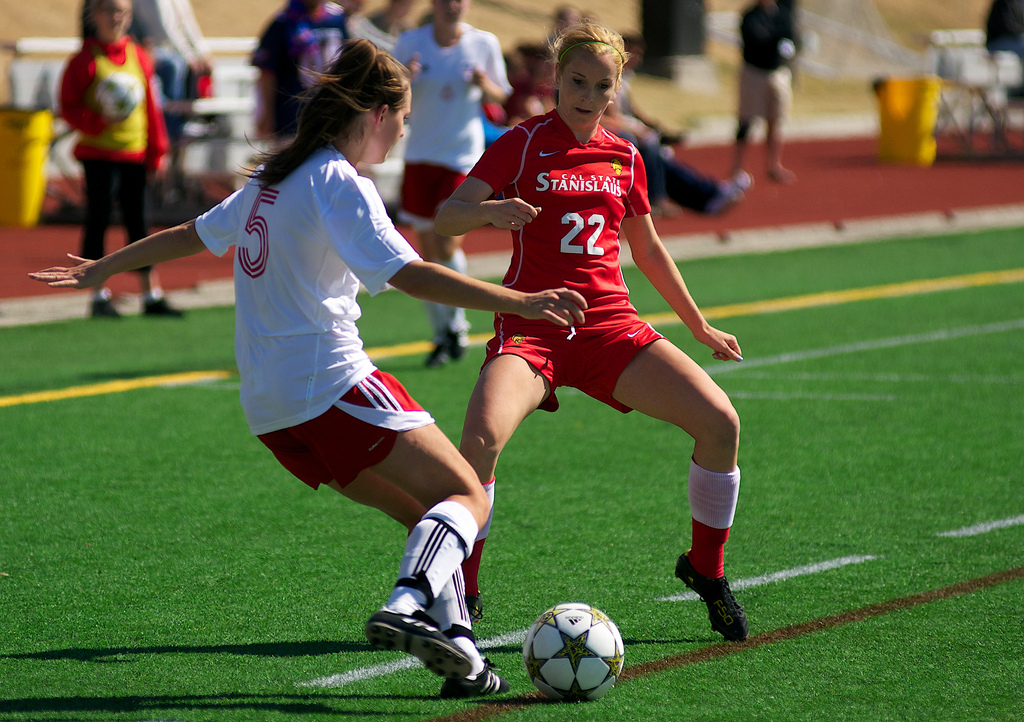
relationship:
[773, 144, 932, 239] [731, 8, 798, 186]
redground under person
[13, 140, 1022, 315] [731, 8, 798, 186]
ground under person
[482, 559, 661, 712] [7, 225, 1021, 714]
ball on ground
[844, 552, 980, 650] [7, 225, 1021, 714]
line on ground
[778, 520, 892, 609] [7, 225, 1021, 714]
line on ground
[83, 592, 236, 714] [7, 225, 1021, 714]
shadow on ground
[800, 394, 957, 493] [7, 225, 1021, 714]
greengrass on ground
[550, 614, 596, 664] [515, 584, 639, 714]
design on ball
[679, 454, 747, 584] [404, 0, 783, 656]
sock on female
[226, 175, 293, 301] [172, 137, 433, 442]
number on jersey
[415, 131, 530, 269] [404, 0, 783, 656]
arm on female